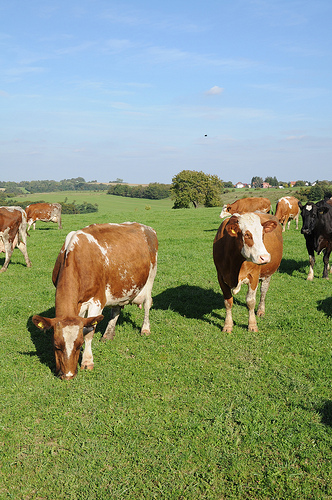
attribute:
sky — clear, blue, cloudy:
[9, 0, 332, 184]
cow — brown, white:
[213, 213, 284, 337]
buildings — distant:
[230, 180, 323, 189]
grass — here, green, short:
[3, 189, 330, 499]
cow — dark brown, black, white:
[299, 196, 332, 284]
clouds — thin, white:
[22, 44, 328, 164]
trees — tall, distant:
[7, 169, 326, 207]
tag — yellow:
[36, 321, 44, 332]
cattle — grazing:
[2, 195, 332, 382]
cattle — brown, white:
[6, 194, 304, 382]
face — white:
[240, 215, 273, 264]